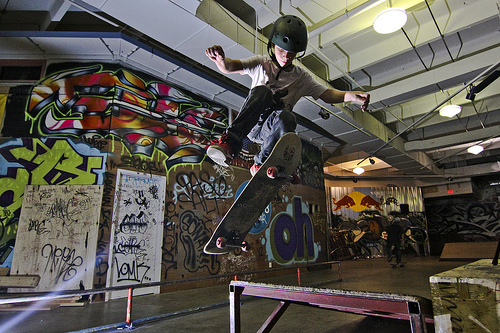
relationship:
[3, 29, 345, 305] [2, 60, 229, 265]
wall with collored graffiti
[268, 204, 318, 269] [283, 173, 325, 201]
word on wall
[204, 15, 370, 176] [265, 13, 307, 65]
boy wearing a helmet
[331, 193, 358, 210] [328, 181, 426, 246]
logo on wall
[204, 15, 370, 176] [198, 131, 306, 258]
boy jumping a skateboard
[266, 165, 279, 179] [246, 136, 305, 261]
wheel of a skateboard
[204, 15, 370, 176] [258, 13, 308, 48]
boy wears helmet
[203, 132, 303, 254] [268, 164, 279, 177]
skate board has wheel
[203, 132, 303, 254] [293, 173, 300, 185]
skate board has wheel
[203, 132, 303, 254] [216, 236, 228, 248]
skate board has wheel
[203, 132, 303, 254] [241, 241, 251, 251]
skate board has wheel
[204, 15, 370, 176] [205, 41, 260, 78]
boy has arm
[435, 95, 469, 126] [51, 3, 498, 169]
light on ceiling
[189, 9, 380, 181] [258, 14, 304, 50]
boy wearing helmet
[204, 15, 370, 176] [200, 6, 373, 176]
boy doing tricks on skateboard